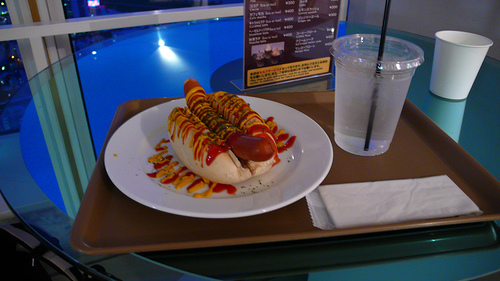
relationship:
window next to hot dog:
[59, 3, 261, 94] [184, 80, 272, 160]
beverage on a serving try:
[330, 32, 425, 156] [68, 89, 500, 254]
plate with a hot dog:
[95, 37, 326, 228] [176, 74, 260, 181]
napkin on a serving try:
[303, 172, 485, 229] [68, 89, 500, 254]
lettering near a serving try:
[244, 1, 342, 90] [68, 89, 500, 254]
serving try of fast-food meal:
[68, 89, 500, 254] [146, 78, 295, 199]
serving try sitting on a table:
[68, 89, 500, 254] [8, 25, 498, 241]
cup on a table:
[429, 30, 493, 101] [8, 12, 484, 275]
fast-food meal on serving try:
[148, 76, 300, 200] [68, 89, 500, 254]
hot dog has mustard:
[184, 78, 275, 162] [189, 85, 234, 143]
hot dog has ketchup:
[184, 78, 275, 162] [199, 137, 231, 166]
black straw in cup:
[363, 0, 393, 151] [327, 22, 425, 162]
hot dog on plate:
[184, 78, 275, 162] [104, 94, 332, 219]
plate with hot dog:
[104, 94, 332, 219] [184, 78, 275, 162]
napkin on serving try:
[303, 172, 485, 229] [68, 89, 500, 254]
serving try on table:
[68, 89, 500, 254] [68, 67, 498, 261]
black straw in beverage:
[375, 0, 395, 58] [330, 32, 425, 156]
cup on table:
[425, 26, 485, 103] [101, 62, 496, 250]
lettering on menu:
[244, 2, 342, 92] [242, 1, 334, 81]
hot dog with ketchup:
[144, 82, 285, 190] [202, 137, 231, 168]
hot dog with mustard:
[144, 82, 285, 190] [186, 90, 256, 136]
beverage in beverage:
[336, 69, 411, 151] [330, 32, 425, 156]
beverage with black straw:
[330, 32, 425, 156] [363, 0, 393, 151]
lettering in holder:
[244, 1, 342, 90] [234, 1, 346, 95]